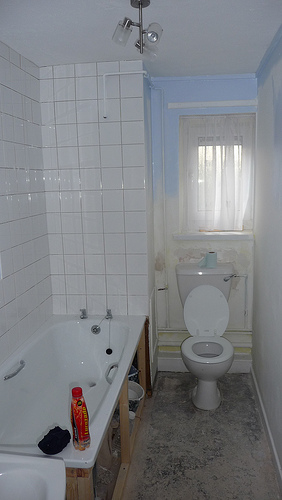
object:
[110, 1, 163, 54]
light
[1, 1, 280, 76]
ceiling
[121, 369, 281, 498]
floor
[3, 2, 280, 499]
bathroom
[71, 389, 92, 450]
bottle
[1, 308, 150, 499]
tub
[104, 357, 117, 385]
handle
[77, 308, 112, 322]
faucet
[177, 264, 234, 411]
toilet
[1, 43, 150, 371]
tile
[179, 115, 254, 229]
curtain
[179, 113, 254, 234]
window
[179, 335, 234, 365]
seat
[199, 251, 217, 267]
paper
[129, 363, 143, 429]
buckets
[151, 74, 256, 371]
wall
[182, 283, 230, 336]
lid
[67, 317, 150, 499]
poles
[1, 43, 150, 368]
wall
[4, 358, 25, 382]
handle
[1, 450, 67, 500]
sink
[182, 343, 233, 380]
bowl